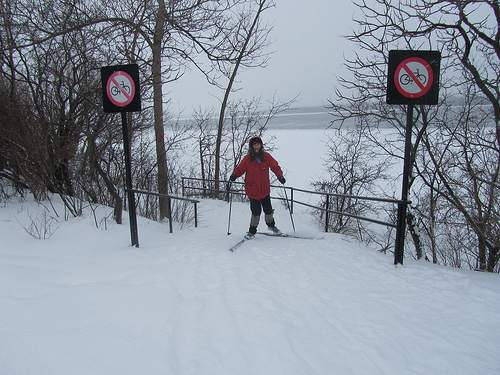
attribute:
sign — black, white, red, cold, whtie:
[95, 62, 139, 117]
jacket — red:
[241, 159, 283, 200]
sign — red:
[390, 51, 443, 109]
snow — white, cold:
[143, 243, 188, 273]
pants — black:
[241, 193, 273, 224]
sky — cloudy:
[297, 22, 339, 66]